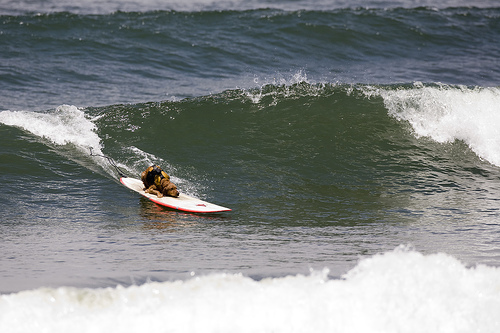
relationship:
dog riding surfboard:
[141, 165, 180, 196] [119, 175, 234, 216]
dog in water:
[140, 159, 179, 200] [3, 2, 499, 263]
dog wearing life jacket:
[140, 159, 179, 200] [145, 165, 168, 189]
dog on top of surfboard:
[140, 159, 179, 200] [119, 175, 234, 216]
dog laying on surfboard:
[140, 159, 179, 200] [119, 175, 234, 216]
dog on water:
[140, 159, 179, 200] [3, 2, 499, 263]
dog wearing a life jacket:
[140, 159, 179, 200] [145, 165, 168, 189]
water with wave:
[3, 2, 499, 263] [3, 80, 499, 198]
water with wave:
[3, 2, 499, 263] [4, 2, 500, 82]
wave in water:
[3, 80, 499, 198] [3, 2, 499, 263]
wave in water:
[4, 2, 500, 82] [3, 2, 499, 263]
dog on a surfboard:
[140, 159, 179, 200] [119, 175, 234, 216]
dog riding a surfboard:
[140, 159, 179, 200] [119, 175, 234, 216]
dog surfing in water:
[140, 159, 179, 200] [0, 0, 499, 333]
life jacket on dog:
[147, 165, 171, 189] [140, 159, 179, 200]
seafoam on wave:
[387, 86, 499, 168] [3, 80, 499, 198]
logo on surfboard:
[196, 201, 207, 209] [119, 175, 234, 216]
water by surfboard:
[3, 2, 499, 263] [119, 175, 234, 216]